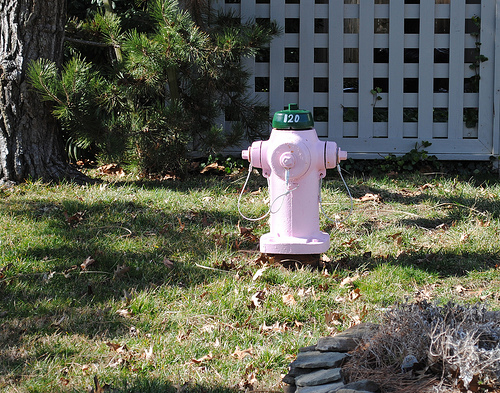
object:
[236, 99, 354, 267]
hydrant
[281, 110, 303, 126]
120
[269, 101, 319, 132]
green top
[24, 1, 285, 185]
bush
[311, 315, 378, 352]
stone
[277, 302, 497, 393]
enclosure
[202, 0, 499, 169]
fence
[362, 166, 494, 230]
shadow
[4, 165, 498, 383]
grass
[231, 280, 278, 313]
plants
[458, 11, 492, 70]
plants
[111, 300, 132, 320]
leaves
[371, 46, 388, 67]
space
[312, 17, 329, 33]
space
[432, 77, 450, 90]
space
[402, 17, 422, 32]
space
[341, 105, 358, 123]
space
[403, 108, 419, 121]
space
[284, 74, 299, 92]
space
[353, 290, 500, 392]
plant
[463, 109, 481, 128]
weed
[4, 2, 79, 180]
trunk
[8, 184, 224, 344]
shadow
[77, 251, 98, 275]
leaf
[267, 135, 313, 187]
valve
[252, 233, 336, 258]
pink base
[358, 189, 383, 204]
leaves